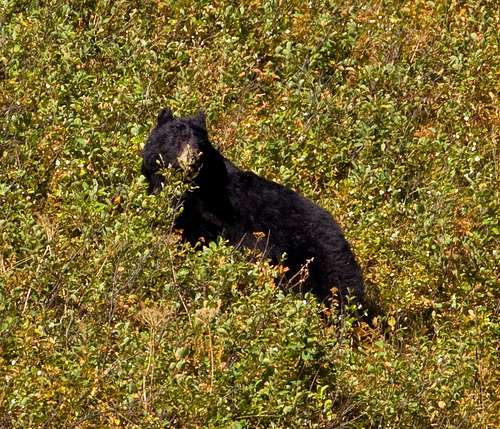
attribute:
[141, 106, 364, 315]
bear — foraging, furry, black, flurry, large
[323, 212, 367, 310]
rear — furry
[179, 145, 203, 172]
snout — brownish, white, brown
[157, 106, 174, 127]
ear — standing up, black, furry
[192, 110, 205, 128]
ear — standing up, black, furry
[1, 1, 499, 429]
leaves — brown, dry, green, yellow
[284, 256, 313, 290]
twig — dry, sticking out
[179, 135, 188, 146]
eye — black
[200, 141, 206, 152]
eye — black